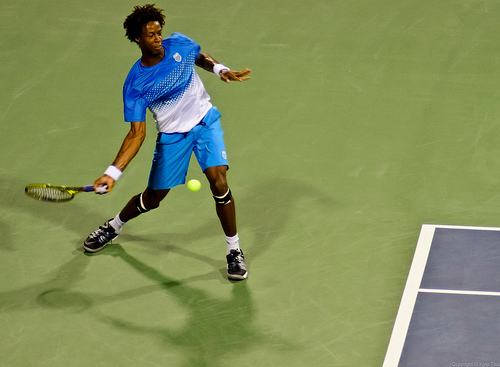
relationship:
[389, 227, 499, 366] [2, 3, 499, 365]
square on top of grass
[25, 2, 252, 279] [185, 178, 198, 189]
player hitting a tennis ball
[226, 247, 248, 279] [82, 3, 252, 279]
shoe of a man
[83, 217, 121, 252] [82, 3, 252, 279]
shoe of a man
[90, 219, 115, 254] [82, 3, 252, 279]
tennis shoe of a man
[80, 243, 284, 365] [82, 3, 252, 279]
shadow of a man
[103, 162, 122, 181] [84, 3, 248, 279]
sweat band of a tennis player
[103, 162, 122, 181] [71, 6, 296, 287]
sweat band of a player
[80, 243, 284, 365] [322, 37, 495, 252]
shadow on court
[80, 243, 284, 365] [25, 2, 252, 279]
shadow of player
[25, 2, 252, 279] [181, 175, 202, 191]
player swinging at ball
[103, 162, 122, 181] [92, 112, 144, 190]
sweat band on arm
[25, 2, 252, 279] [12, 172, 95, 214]
player holds racket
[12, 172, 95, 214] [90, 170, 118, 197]
racket in hand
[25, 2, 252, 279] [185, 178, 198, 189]
player about to hit tennis ball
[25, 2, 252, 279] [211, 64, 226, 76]
player wearing wrist band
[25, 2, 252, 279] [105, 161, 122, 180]
player wearing wrist band